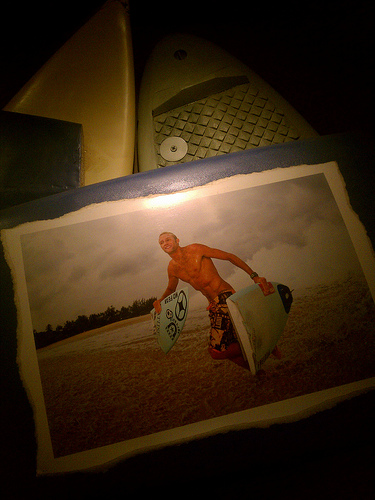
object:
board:
[0, 0, 323, 212]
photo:
[0, 160, 375, 474]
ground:
[84, 330, 236, 407]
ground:
[33, 259, 374, 459]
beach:
[59, 334, 211, 398]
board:
[225, 279, 293, 375]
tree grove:
[30, 294, 155, 350]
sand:
[33, 278, 373, 460]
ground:
[37, 280, 373, 455]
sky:
[19, 170, 358, 335]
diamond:
[153, 83, 305, 173]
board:
[147, 67, 316, 173]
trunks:
[202, 289, 245, 352]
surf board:
[150, 281, 294, 375]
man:
[153, 232, 281, 380]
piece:
[146, 287, 195, 357]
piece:
[224, 281, 294, 377]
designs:
[150, 285, 190, 355]